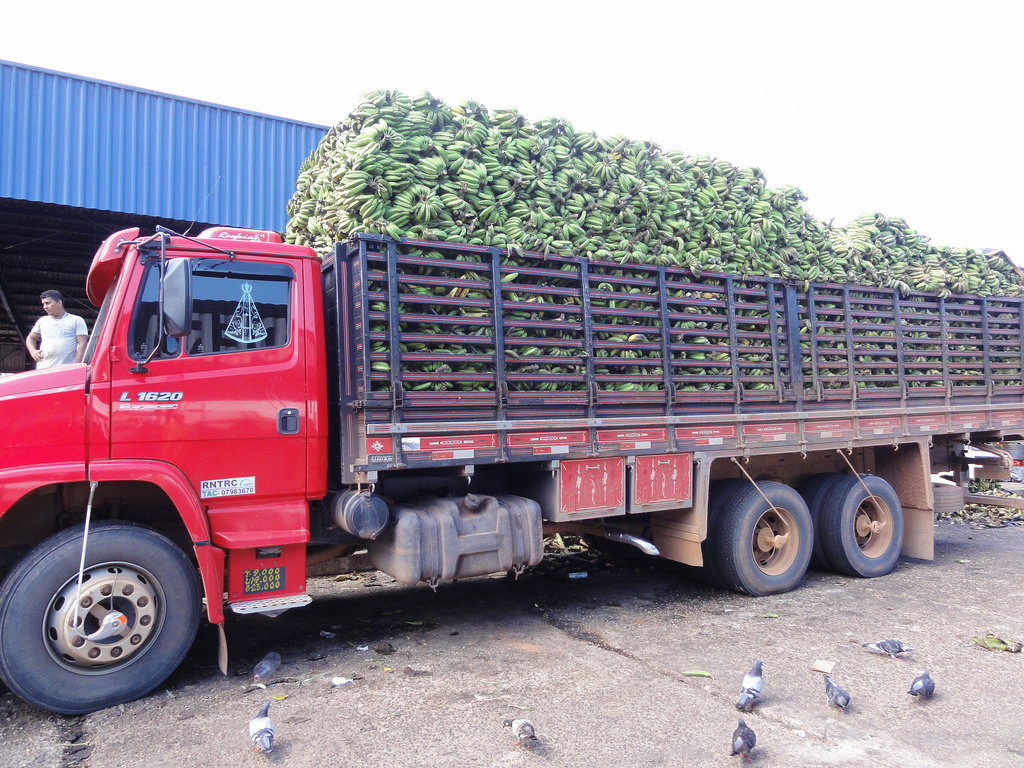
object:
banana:
[441, 142, 537, 240]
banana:
[614, 293, 701, 376]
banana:
[380, 237, 486, 354]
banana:
[736, 310, 816, 348]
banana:
[900, 240, 939, 294]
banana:
[284, 86, 1021, 406]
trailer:
[321, 224, 1024, 599]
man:
[25, 289, 88, 381]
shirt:
[32, 312, 90, 370]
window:
[128, 258, 293, 363]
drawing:
[224, 280, 270, 344]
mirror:
[162, 255, 195, 337]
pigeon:
[726, 720, 758, 767]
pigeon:
[503, 720, 538, 750]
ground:
[0, 438, 1022, 768]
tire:
[0, 520, 205, 717]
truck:
[0, 90, 1021, 716]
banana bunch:
[410, 148, 449, 191]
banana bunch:
[343, 186, 390, 221]